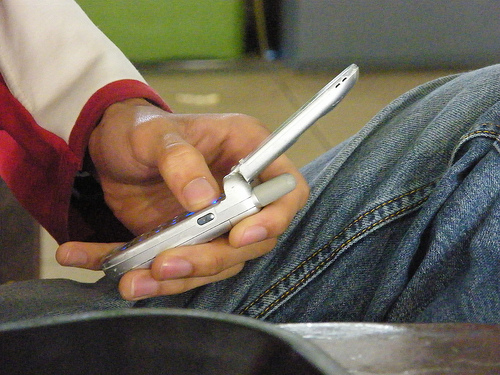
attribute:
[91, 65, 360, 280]
cell phone — silver, flip phone, gre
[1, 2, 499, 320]
person — white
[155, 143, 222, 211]
thumb — big, pressig buttons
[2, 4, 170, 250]
sleeve — dark red, red, white, red ad white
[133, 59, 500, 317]
jeans — fading, blue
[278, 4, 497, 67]
wall — gra, gre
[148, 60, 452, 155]
ground — ta, brown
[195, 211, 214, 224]
button — silver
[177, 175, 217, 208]
nail — short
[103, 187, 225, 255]
light — blue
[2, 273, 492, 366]
table — brow